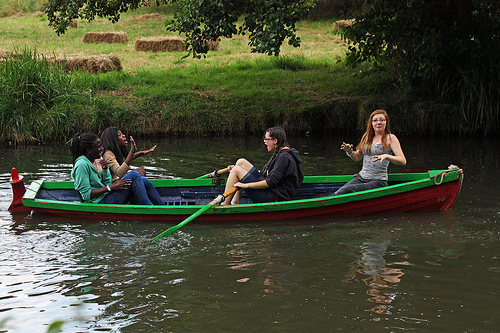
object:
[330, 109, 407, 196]
women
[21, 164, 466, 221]
row boat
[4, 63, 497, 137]
shore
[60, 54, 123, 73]
haystack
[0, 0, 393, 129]
field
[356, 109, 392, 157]
hair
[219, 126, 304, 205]
woman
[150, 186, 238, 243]
oar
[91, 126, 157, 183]
woman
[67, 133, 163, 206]
woman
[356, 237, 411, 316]
woman's reflection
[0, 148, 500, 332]
water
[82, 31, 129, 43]
haystack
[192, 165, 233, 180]
oar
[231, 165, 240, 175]
knees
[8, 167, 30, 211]
rutter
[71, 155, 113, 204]
sweatshirt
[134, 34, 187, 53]
bale of hay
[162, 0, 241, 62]
tree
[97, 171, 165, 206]
jeans